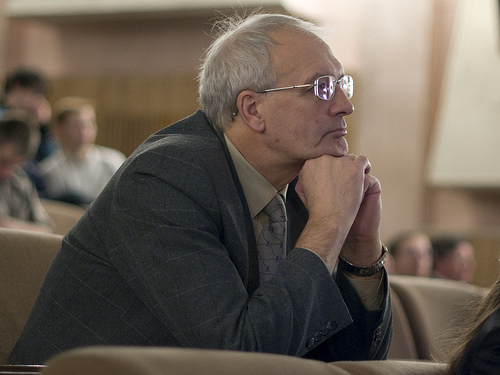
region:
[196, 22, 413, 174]
the head of a man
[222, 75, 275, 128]
the ear of a man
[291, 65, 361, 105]
the eye of a man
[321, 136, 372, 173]
the chin of a man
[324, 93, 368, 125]
the nose of a man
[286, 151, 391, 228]
the hands of a man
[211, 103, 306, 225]
the neck of a man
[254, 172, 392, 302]
the wrist of a man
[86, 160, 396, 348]
the arm of a man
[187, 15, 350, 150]
the hair of a man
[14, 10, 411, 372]
this is a person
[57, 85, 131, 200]
this is a person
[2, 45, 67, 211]
this is a person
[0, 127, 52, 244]
this is a person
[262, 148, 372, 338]
the hand of a person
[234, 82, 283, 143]
the ear of a person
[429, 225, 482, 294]
this is a person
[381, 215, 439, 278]
this is a person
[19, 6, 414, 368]
A man sitting pensively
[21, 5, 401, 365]
A man sitting pensively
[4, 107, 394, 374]
Grey men's dress jacket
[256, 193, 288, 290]
Men's tie with minimal design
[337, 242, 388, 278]
Metal wristband on men's watch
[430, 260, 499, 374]
Brown hair in corner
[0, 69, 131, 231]
People sitting a few rows back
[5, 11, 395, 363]
A man paying close attention to something in front of him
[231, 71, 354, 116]
Eyeglasses on a man's face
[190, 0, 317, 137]
Grey short hair on a man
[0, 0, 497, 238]
Light colored wall in back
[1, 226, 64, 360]
Light brown seat cushion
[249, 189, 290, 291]
a gray tie with black design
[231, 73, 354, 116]
wire-framed glasses on a face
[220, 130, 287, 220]
a tan-colored dress shirt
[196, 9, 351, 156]
an older man with short gray hair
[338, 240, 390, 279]
a watch being worn on a wrist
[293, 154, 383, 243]
fingers folded on hands crossed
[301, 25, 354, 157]
a man looking pensive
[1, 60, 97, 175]
a crowd of spectators in the background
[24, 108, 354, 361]
a pin-striped gray suitcoat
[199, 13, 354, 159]
a man listening intently toward the right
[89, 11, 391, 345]
the man is wearing glasses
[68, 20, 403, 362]
the man is wearing a grey suit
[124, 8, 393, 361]
one man sitting down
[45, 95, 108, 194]
the man is wearing a white shirt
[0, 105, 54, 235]
man with his head down